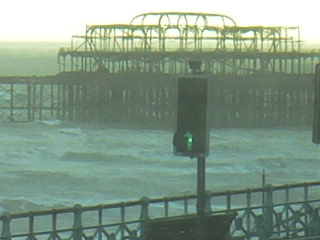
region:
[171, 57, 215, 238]
black traffic signal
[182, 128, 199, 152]
green go arrow on traffic signal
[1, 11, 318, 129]
bridge over the water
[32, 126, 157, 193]
choppy waves in ocean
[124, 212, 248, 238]
a bench by the water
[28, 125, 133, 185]
the water is gray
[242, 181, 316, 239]
a fence by the water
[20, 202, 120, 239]
the fence is gray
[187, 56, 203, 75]
camera on top of the traffic signal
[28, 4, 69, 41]
the sky is white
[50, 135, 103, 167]
Water along the walkway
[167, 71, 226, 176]
Traffic light near the water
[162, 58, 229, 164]
Traffic light with a green light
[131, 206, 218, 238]
Park bench along the water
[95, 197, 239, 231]
Railing along the water way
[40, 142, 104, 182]
Ruff water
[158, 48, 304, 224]
Traffic intersection near the water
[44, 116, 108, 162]
Ruff white caps on the water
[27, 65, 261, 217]
Waves coming in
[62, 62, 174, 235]
Walkway with rainy weather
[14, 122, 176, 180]
water is murky and green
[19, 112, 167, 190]
water is murky and green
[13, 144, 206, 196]
water is murky and green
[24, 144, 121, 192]
water is murky and green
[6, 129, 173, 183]
water is murky and green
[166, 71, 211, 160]
traffice sign is black light is green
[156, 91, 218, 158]
traffic sign is black light is green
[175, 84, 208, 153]
traffic sign is black light is green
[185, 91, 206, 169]
traffic sign is black light is green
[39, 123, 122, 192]
the water is blue green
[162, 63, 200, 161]
green signal light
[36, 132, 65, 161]
rough gray waves in ocean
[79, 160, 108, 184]
rough gray waves in ocean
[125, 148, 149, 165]
rough gray waves in ocean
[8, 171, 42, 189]
rough gray waves in ocean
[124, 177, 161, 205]
rough gray waves in ocean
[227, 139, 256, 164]
rough gray waves in ocean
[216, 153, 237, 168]
rough gray waves in ocean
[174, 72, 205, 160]
signal light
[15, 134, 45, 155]
rough waves in gray water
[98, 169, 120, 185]
rough waves in gray water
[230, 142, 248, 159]
rough waves in gray water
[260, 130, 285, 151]
rough waves in gray water